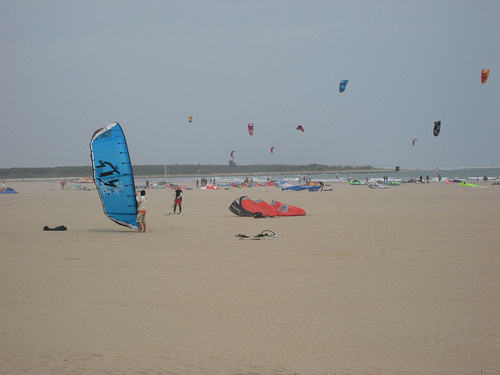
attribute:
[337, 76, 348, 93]
kite — large, flying, blue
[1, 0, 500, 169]
sky — hazy, blue, clear, air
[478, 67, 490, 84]
kite — large, flying, red, orange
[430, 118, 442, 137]
kite — large, flying, black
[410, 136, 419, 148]
kite — large, flying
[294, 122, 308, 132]
kite — large, flying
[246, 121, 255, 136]
kite — colorful, yellow, large, flying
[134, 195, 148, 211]
shirt — white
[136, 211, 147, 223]
shorts — tan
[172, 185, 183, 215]
person — woman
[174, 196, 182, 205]
shorts — orange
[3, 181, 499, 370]
beach — sandy, shore, flat, ground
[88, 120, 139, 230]
kite — sail, large, blue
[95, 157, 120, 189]
design — black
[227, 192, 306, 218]
kite — sail, red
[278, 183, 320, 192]
kite — blue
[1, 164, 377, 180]
vegetation — green, distant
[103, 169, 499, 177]
bay — water